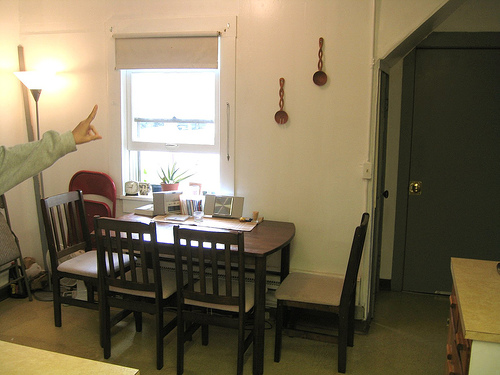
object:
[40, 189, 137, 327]
chair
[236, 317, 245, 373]
leg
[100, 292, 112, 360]
leg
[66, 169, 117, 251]
chair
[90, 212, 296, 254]
table top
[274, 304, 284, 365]
leg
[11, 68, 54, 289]
lamp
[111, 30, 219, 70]
shade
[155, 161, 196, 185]
plant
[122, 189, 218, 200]
windowsill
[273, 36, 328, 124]
spoons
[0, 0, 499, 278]
wall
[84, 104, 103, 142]
fingers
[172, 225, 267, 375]
chair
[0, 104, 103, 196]
person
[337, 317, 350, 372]
leg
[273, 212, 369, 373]
chair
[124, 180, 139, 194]
clock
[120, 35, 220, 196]
window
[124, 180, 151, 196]
sill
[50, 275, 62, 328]
leg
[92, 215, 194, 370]
chair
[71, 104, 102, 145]
hand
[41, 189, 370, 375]
four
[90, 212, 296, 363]
table